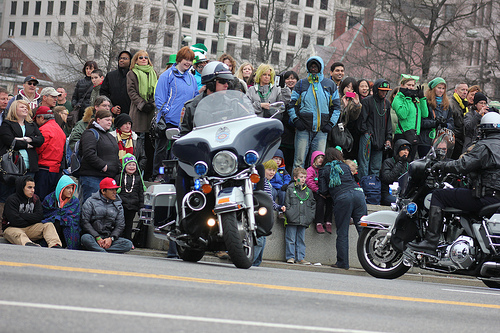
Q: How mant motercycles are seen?
A: Two.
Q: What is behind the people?
A: Buildings.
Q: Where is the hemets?
A: On their heads.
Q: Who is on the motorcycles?
A: Police.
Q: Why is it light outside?
A: Its daytime.